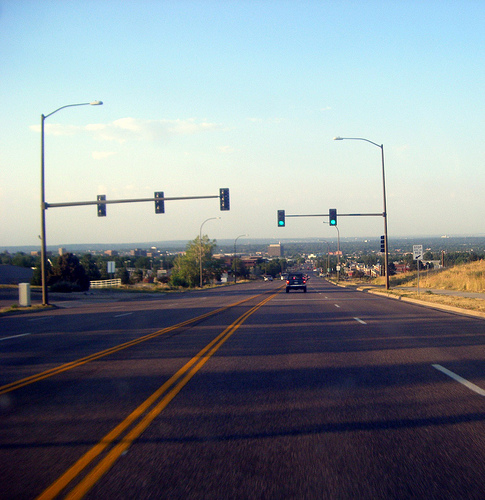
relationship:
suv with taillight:
[267, 256, 318, 304] [285, 278, 290, 285]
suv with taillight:
[267, 256, 318, 304] [303, 279, 306, 285]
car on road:
[285, 268, 307, 292] [3, 309, 477, 453]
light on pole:
[216, 185, 231, 209] [40, 186, 231, 215]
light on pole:
[151, 187, 166, 218] [40, 186, 231, 215]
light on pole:
[93, 191, 108, 219] [40, 186, 231, 215]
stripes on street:
[432, 360, 483, 397] [1, 272, 470, 496]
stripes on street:
[332, 302, 342, 309] [1, 272, 470, 496]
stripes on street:
[113, 309, 135, 318] [1, 272, 470, 496]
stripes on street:
[165, 302, 178, 308] [1, 272, 470, 496]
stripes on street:
[0, 330, 33, 341] [1, 272, 470, 496]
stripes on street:
[323, 294, 330, 301] [1, 272, 470, 496]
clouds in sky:
[70, 145, 104, 167] [0, 0, 485, 246]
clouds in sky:
[106, 121, 207, 152] [0, 0, 485, 246]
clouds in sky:
[167, 86, 453, 224] [0, 0, 485, 246]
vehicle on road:
[278, 254, 311, 299] [0, 261, 483, 497]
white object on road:
[16, 272, 43, 317] [0, 261, 483, 497]